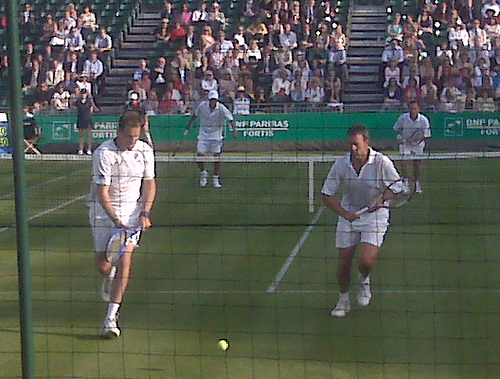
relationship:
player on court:
[170, 87, 237, 187] [1, 150, 498, 375]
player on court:
[392, 98, 430, 192] [1, 150, 498, 375]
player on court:
[83, 110, 155, 337] [1, 150, 498, 375]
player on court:
[320, 122, 406, 316] [1, 150, 498, 375]